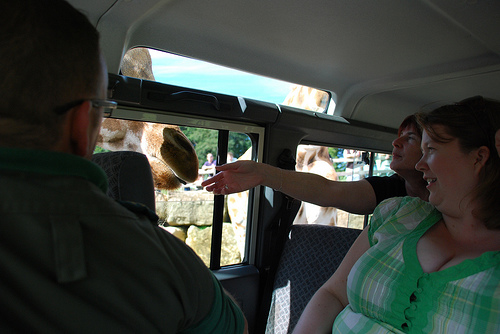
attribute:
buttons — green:
[407, 278, 426, 306]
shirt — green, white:
[332, 193, 499, 333]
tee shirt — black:
[362, 165, 425, 204]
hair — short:
[0, 2, 107, 147]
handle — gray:
[106, 67, 281, 130]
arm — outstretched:
[256, 163, 396, 215]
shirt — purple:
[200, 162, 216, 170]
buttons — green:
[398, 272, 426, 332]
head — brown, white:
[95, 43, 201, 189]